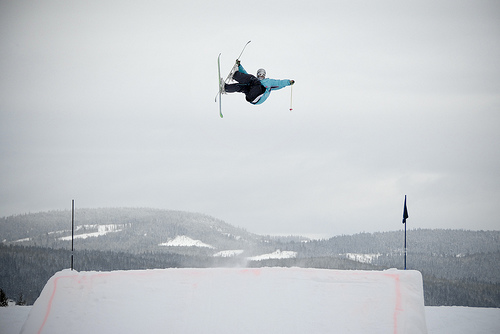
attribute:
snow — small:
[2, 276, 497, 331]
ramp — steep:
[28, 270, 422, 331]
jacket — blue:
[255, 76, 298, 107]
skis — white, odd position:
[212, 34, 253, 126]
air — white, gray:
[13, 3, 492, 203]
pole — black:
[70, 196, 79, 270]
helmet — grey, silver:
[255, 69, 268, 77]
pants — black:
[223, 74, 264, 102]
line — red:
[389, 275, 408, 329]